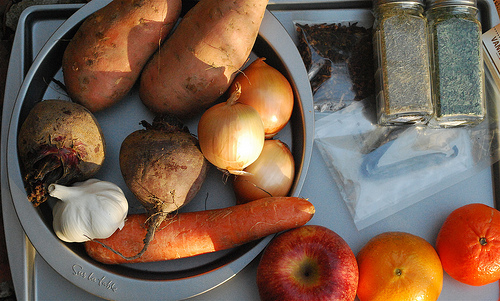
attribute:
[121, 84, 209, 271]
yam — large , pink 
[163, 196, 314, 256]
carrot — picked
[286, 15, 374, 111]
herbs — small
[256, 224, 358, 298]
apple — red , yellow 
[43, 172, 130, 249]
clove — white 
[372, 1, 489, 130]
shaker — pepper, herb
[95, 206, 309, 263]
carrot — orange 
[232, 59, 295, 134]
onion — ripe, yellow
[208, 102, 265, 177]
onion — yellow 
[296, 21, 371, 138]
packet — herbs